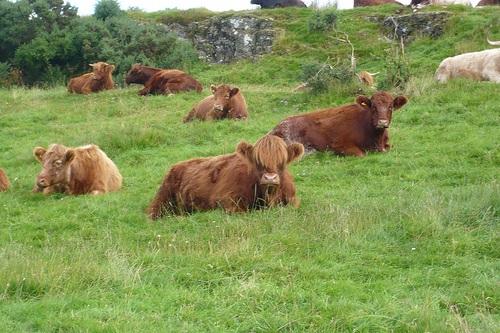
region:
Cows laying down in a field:
[36, 47, 399, 224]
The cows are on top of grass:
[48, 53, 407, 242]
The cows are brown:
[31, 50, 411, 254]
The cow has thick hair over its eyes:
[219, 131, 317, 198]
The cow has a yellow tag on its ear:
[351, 89, 373, 112]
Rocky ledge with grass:
[183, 17, 455, 76]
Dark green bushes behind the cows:
[14, 6, 231, 98]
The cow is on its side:
[179, 78, 259, 138]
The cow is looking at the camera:
[299, 91, 411, 157]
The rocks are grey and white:
[178, 11, 294, 74]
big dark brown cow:
[294, 94, 402, 169]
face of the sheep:
[349, 80, 398, 135]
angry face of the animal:
[251, 151, 295, 210]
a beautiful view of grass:
[48, 86, 499, 328]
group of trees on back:
[45, 11, 335, 107]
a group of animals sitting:
[43, 39, 451, 261]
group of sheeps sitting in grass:
[4, 30, 481, 265]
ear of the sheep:
[237, 129, 252, 162]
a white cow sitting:
[428, 30, 491, 80]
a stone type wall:
[177, 3, 425, 94]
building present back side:
[155, 1, 478, 38]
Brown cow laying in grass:
[173, 82, 254, 131]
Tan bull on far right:
[428, 37, 498, 89]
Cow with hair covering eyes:
[228, 134, 307, 203]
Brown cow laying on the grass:
[15, 133, 128, 210]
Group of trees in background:
[1, 0, 201, 91]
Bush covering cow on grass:
[282, 41, 386, 108]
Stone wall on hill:
[154, 14, 281, 79]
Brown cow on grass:
[117, 58, 206, 108]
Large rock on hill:
[366, 6, 463, 57]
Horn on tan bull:
[472, 20, 499, 59]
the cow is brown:
[120, 87, 333, 234]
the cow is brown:
[156, 130, 283, 227]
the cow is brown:
[78, 23, 325, 300]